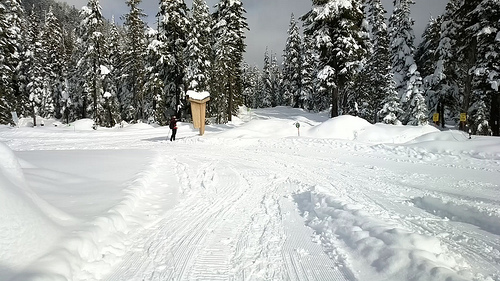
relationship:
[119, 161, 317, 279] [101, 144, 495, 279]
tracks on path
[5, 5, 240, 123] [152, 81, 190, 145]
snow on evergreens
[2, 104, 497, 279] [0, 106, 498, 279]
snow on ground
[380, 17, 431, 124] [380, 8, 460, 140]
snow on tree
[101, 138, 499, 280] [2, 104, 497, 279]
path on snow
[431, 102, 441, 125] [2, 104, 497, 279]
pillar on snow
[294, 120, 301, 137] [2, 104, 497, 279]
marker pole on snow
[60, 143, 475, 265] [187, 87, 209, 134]
snow on pillar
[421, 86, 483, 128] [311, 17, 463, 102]
signs under trees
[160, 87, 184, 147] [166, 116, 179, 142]
person wearing snowsuit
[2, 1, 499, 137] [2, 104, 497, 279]
trees in snow